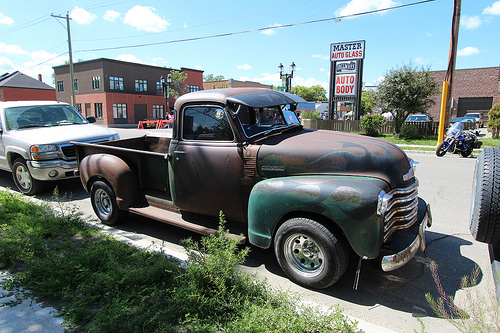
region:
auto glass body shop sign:
[325, 40, 368, 131]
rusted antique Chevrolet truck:
[106, 93, 423, 275]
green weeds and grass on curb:
[48, 207, 235, 332]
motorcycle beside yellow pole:
[429, 112, 489, 162]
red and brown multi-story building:
[52, 64, 203, 120]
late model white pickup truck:
[0, 90, 81, 195]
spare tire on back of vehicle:
[468, 133, 497, 265]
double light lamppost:
[250, 57, 308, 101]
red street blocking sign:
[130, 112, 175, 132]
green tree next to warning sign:
[155, 67, 193, 129]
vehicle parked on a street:
[61, 75, 447, 297]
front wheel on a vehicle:
[268, 206, 358, 296]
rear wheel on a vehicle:
[83, 173, 129, 227]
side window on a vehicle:
[174, 97, 241, 149]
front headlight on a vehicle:
[32, 140, 66, 165]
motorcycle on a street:
[433, 115, 488, 162]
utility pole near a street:
[46, 7, 87, 114]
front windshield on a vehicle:
[1, 98, 94, 134]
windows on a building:
[103, 70, 128, 92]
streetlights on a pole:
[273, 58, 299, 80]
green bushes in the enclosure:
[163, 228, 248, 287]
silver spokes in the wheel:
[283, 238, 338, 274]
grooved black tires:
[268, 215, 347, 295]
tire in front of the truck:
[463, 144, 491, 246]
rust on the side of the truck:
[325, 181, 367, 211]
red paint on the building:
[88, 89, 148, 118]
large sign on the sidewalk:
[321, 39, 368, 114]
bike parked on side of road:
[420, 114, 485, 159]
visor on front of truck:
[224, 81, 321, 120]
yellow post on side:
[428, 71, 450, 146]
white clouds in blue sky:
[16, 7, 49, 62]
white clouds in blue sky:
[113, 2, 152, 30]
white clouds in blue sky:
[152, 18, 212, 60]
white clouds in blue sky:
[216, 21, 283, 54]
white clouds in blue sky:
[281, 2, 352, 41]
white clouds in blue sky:
[336, 0, 391, 25]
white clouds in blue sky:
[384, 14, 430, 56]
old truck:
[97, 77, 398, 300]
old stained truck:
[111, 84, 375, 251]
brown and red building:
[70, 54, 137, 112]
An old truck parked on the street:
[65, 75, 443, 297]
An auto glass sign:
[325, 37, 377, 65]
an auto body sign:
[326, 68, 364, 103]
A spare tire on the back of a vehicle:
[465, 136, 498, 251]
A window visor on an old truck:
[223, 83, 312, 120]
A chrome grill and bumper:
[370, 148, 440, 281]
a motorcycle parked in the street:
[429, 115, 486, 160]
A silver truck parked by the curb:
[2, 90, 121, 212]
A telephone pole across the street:
[34, 4, 101, 98]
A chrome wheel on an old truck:
[267, 208, 342, 290]